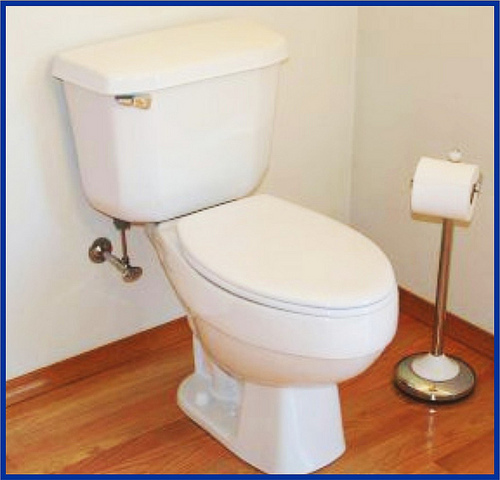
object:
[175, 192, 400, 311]
lid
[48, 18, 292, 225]
tank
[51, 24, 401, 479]
toilet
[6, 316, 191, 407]
baseboard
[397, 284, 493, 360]
baseboard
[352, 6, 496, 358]
wall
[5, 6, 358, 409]
wall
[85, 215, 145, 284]
pipes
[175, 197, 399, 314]
seat cover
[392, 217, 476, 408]
paper holder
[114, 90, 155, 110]
handle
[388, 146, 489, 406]
holder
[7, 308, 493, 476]
hardwood floor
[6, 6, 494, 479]
bathroom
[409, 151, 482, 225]
toilet paper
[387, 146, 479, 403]
stand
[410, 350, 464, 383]
base